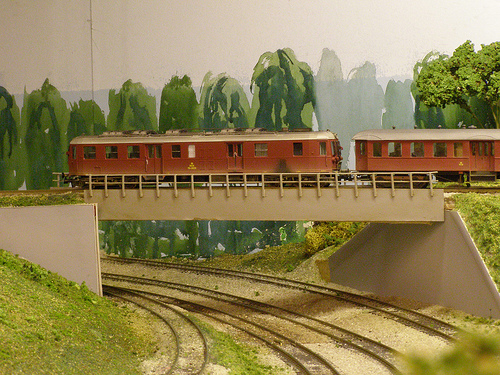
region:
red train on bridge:
[52, 131, 497, 181]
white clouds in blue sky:
[14, 15, 75, 46]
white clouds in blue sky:
[24, 22, 81, 70]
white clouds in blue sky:
[121, 11, 161, 45]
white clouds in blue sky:
[58, 31, 99, 68]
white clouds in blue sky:
[162, 13, 203, 67]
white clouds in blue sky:
[211, 6, 248, 61]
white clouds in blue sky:
[255, 9, 297, 50]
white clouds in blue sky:
[325, 8, 389, 53]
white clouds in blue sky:
[381, 6, 445, 46]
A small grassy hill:
[1, 249, 126, 373]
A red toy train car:
[67, 124, 344, 186]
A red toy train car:
[351, 127, 498, 182]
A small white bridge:
[47, 170, 447, 227]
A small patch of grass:
[191, 311, 279, 373]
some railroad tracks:
[98, 252, 480, 373]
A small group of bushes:
[306, 221, 358, 250]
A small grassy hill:
[206, 232, 350, 274]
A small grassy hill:
[456, 190, 499, 287]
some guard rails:
[55, 170, 442, 194]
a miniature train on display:
[48, 122, 498, 221]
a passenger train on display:
[57, 119, 496, 193]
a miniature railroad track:
[87, 240, 491, 374]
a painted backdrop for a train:
[3, 8, 430, 190]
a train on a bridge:
[44, 129, 459, 271]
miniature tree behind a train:
[405, 37, 498, 159]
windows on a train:
[77, 139, 144, 161]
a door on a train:
[139, 140, 169, 179]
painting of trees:
[2, 33, 314, 164]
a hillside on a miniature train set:
[3, 233, 123, 374]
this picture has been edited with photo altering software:
[25, 57, 485, 363]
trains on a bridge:
[34, 100, 485, 215]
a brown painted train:
[64, 116, 356, 178]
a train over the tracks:
[346, 119, 499, 180]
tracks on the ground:
[114, 247, 456, 369]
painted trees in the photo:
[14, 17, 469, 123]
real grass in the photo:
[9, 252, 141, 347]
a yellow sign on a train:
[183, 157, 209, 176]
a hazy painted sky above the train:
[54, 7, 444, 53]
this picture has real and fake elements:
[27, 34, 271, 302]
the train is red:
[63, 100, 495, 183]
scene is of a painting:
[0, 0, 499, 374]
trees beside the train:
[2, 8, 483, 285]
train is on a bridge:
[49, 110, 494, 232]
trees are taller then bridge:
[2, 14, 497, 231]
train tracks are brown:
[101, 255, 473, 373]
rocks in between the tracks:
[93, 245, 469, 374]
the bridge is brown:
[51, 169, 448, 244]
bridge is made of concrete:
[54, 156, 454, 235]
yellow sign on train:
[178, 156, 216, 171]